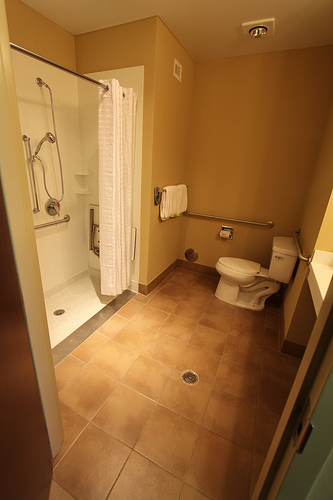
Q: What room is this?
A: It is a bathroom.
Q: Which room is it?
A: It is a bathroom.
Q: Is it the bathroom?
A: Yes, it is the bathroom.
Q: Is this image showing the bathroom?
A: Yes, it is showing the bathroom.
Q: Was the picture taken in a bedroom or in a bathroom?
A: It was taken at a bathroom.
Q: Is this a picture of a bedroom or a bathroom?
A: It is showing a bathroom.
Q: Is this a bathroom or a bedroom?
A: It is a bathroom.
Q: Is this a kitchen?
A: No, it is a bathroom.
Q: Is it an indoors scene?
A: Yes, it is indoors.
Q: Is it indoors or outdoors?
A: It is indoors.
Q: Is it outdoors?
A: No, it is indoors.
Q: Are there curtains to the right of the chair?
A: Yes, there is a curtain to the right of the chair.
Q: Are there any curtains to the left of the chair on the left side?
A: No, the curtain is to the right of the chair.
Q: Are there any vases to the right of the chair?
A: No, there is a curtain to the right of the chair.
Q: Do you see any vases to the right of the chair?
A: No, there is a curtain to the right of the chair.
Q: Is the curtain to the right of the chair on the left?
A: Yes, the curtain is to the right of the chair.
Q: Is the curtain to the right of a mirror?
A: No, the curtain is to the right of the chair.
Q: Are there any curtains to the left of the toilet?
A: Yes, there is a curtain to the left of the toilet.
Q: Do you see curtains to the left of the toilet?
A: Yes, there is a curtain to the left of the toilet.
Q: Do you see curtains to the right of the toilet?
A: No, the curtain is to the left of the toilet.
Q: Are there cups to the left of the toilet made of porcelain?
A: No, there is a curtain to the left of the toilet.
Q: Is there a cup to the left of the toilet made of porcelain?
A: No, there is a curtain to the left of the toilet.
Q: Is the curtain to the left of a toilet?
A: Yes, the curtain is to the left of a toilet.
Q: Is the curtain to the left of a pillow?
A: No, the curtain is to the left of a toilet.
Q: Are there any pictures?
A: No, there are no pictures.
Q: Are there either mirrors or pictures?
A: No, there are no pictures or mirrors.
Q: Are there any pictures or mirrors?
A: No, there are no pictures or mirrors.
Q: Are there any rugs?
A: No, there are no rugs.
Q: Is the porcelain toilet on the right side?
A: Yes, the toilet is on the right of the image.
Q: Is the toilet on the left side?
A: No, the toilet is on the right of the image.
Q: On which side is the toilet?
A: The toilet is on the right of the image.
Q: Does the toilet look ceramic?
A: Yes, the toilet is ceramic.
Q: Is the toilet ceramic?
A: Yes, the toilet is ceramic.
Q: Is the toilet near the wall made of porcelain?
A: Yes, the toilet is made of porcelain.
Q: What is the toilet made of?
A: The toilet is made of porcelain.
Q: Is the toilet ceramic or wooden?
A: The toilet is ceramic.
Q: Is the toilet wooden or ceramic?
A: The toilet is ceramic.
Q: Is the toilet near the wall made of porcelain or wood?
A: The toilet is made of porcelain.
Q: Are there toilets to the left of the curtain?
A: No, the toilet is to the right of the curtain.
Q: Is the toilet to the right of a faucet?
A: No, the toilet is to the right of the curtain.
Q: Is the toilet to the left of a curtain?
A: No, the toilet is to the right of a curtain.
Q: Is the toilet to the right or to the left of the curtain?
A: The toilet is to the right of the curtain.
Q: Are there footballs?
A: No, there are no footballs.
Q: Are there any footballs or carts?
A: No, there are no footballs or carts.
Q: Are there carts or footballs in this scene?
A: No, there are no footballs or carts.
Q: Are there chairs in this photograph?
A: Yes, there is a chair.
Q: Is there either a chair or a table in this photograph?
A: Yes, there is a chair.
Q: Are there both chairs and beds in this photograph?
A: No, there is a chair but no beds.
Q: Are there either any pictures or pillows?
A: No, there are no pictures or pillows.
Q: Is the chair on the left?
A: Yes, the chair is on the left of the image.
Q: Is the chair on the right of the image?
A: No, the chair is on the left of the image.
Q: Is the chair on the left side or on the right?
A: The chair is on the left of the image.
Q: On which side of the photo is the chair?
A: The chair is on the left of the image.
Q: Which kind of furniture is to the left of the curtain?
A: The piece of furniture is a chair.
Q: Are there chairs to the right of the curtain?
A: No, the chair is to the left of the curtain.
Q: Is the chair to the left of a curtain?
A: Yes, the chair is to the left of a curtain.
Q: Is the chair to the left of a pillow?
A: No, the chair is to the left of a curtain.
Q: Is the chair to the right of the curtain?
A: No, the chair is to the left of the curtain.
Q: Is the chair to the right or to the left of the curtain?
A: The chair is to the left of the curtain.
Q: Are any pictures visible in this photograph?
A: No, there are no pictures.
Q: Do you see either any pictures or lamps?
A: No, there are no pictures or lamps.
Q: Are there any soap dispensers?
A: No, there are no soap dispensers.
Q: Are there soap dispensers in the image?
A: No, there are no soap dispensers.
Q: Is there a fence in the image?
A: No, there are no fences.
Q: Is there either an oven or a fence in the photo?
A: No, there are no fences or ovens.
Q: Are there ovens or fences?
A: No, there are no fences or ovens.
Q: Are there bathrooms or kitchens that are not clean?
A: No, there is a bathroom but it is clean.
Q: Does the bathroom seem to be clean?
A: Yes, the bathroom is clean.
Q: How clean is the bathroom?
A: The bathroom is clean.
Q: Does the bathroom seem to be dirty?
A: No, the bathroom is clean.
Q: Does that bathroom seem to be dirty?
A: No, the bathroom is clean.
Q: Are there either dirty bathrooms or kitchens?
A: No, there is a bathroom but it is clean.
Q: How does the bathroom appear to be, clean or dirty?
A: The bathroom is clean.